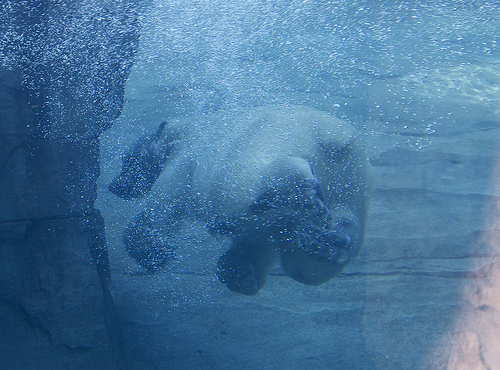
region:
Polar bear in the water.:
[95, 74, 409, 319]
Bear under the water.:
[59, 77, 460, 336]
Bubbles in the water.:
[72, 17, 343, 261]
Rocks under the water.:
[70, 47, 465, 362]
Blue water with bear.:
[110, 94, 394, 303]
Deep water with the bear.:
[62, 24, 471, 287]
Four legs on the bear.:
[87, 164, 498, 306]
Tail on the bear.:
[276, 67, 465, 242]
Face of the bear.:
[103, 115, 169, 252]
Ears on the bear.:
[144, 104, 232, 159]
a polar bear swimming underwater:
[103, 99, 379, 292]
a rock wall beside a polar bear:
[3, 11, 114, 368]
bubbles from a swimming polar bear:
[11, 10, 488, 131]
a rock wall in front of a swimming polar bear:
[102, 6, 496, 363]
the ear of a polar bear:
[150, 116, 175, 142]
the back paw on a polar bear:
[257, 150, 323, 245]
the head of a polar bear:
[95, 115, 178, 198]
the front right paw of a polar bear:
[205, 247, 270, 292]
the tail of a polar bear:
[312, 117, 358, 164]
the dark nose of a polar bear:
[104, 170, 136, 197]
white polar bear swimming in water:
[107, 100, 373, 292]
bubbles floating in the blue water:
[165, 32, 225, 63]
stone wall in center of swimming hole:
[0, 0, 147, 365]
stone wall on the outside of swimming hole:
[95, 0, 495, 365]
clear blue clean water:
[257, 313, 326, 350]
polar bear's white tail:
[314, 129, 356, 161]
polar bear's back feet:
[246, 177, 355, 264]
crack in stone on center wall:
[2, 217, 107, 227]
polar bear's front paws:
[121, 212, 262, 294]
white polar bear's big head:
[105, 118, 168, 201]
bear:
[119, 104, 374, 304]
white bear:
[123, 106, 358, 283]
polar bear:
[122, 99, 354, 278]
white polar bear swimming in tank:
[121, 108, 360, 294]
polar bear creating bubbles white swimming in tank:
[127, 98, 363, 304]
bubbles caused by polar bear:
[21, 14, 128, 106]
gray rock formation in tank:
[22, 128, 99, 346]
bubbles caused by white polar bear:
[179, 6, 478, 82]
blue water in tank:
[395, 95, 465, 288]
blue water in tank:
[148, 300, 378, 362]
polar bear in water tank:
[129, 106, 374, 292]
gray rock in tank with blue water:
[10, 7, 90, 328]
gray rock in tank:
[6, 27, 94, 342]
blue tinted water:
[158, 294, 408, 353]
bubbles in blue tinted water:
[149, 2, 386, 103]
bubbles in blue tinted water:
[309, 10, 495, 98]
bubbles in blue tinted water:
[373, 37, 482, 201]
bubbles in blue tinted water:
[376, 182, 490, 346]